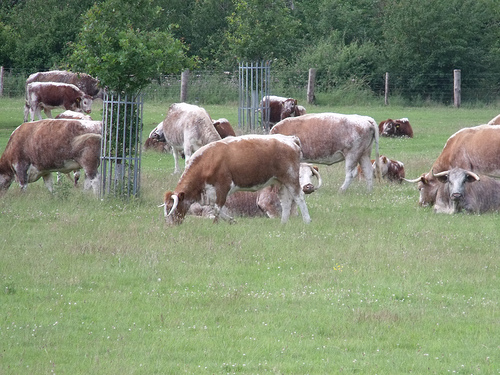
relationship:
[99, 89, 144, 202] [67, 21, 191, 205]
fence around tree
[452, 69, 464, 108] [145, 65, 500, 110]
pole supporting fence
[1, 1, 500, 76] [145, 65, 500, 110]
trees behind fence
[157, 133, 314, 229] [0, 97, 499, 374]
cow eating grass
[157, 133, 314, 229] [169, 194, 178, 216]
cow has horn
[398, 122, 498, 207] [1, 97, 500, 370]
cow grazing in field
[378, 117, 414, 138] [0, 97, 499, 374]
cow lying in grass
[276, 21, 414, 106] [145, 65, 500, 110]
bushes behind fence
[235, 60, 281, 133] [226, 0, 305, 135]
fence around tree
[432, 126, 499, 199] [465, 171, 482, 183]
cow has horn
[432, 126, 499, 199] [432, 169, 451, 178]
cow has horn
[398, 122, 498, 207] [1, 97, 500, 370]
cow in field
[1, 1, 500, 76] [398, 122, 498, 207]
trees behind cow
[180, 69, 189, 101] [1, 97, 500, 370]
pole in field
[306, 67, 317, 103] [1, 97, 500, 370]
pole in field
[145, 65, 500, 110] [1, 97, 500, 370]
fence along field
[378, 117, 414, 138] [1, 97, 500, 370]
cow lying in field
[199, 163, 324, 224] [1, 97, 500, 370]
cow lying in field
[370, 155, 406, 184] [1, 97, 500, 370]
cow lying in field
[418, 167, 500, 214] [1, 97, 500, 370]
cow lying in field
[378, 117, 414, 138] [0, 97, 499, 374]
cow lying on grass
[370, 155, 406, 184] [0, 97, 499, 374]
cow lying on grass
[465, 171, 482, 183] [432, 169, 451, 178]
horn next to horn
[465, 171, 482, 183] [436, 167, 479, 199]
horn on head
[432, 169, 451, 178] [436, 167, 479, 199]
horn on head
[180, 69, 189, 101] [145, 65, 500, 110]
pole supporting fence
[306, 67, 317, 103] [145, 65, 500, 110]
pole supporting fence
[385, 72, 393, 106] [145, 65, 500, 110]
pole supporting fence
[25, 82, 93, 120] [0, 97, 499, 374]
cow eating grass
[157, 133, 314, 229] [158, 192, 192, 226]
cow has head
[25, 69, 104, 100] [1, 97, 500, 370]
cow grazing in field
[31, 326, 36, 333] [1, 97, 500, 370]
flower growing in field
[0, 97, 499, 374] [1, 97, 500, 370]
grass growing in field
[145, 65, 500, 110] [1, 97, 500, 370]
fence around field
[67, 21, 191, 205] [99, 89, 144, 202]
tree behind fence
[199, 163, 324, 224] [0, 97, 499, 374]
cow lying in grass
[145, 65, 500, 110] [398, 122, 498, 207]
fence behind cow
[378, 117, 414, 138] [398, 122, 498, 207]
cow behind cow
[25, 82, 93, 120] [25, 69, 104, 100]
cow in front of cow